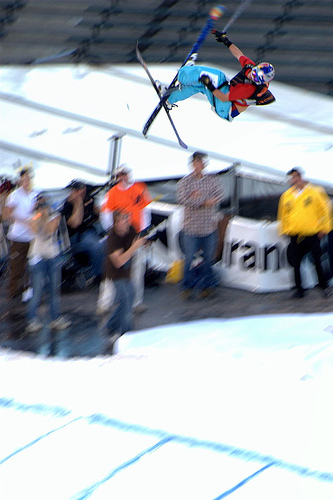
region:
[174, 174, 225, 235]
person is wearing a plaid shirt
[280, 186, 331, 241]
person is wearing a yellow jacket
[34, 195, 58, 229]
person is taking a picture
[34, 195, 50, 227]
person is holding a camera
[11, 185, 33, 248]
person is wearing a white shirt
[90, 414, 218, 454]
blue lines in the snow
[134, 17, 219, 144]
skis are crossed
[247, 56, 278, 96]
person is wearing a helmet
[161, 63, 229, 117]
person is wearing blue pants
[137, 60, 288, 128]
person is in the air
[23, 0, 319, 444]
person doing trick on skis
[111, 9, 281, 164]
blue skis are crossed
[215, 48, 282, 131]
person wearing red shirt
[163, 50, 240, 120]
person wearing blue pants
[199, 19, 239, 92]
person wearing black gloves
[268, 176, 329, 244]
person wearing yellow shirt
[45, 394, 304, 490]
blue lines on snow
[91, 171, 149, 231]
person wearing orange shirt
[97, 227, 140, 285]
person wearing brown shirt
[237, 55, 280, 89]
skier wearing blue shirt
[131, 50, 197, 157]
The mans crossed skis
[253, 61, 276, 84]
The mans helmet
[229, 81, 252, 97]
The sleeve of the mans red shirt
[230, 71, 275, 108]
The orange and black part of the mans shirt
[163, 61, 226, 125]
The mans bright blue pants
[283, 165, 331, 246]
A man with a yellow jacket on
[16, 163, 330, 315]
A crowd of people watching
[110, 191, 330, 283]
A sign with an advertisement or logo on it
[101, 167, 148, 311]
A man in an orange shirt watching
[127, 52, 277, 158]
A skier performing a trick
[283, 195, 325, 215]
Yellow and block jacket on a man.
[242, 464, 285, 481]
Yellow and block jacket on a man.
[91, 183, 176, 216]
Yellow and block jacket on a man.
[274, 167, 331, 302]
man wearing a bright yellow shirt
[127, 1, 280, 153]
skier doing airborne stunts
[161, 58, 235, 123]
bright blue ski pants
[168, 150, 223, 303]
man wearing plaid shirt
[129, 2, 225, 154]
dark blue set of skis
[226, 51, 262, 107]
bright red tee shirt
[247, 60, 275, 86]
shiny blue and silver ski helmet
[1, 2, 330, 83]
blurry empty bleachers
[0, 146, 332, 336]
group of people watching the skier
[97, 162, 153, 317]
man wearing a bright orange shirt